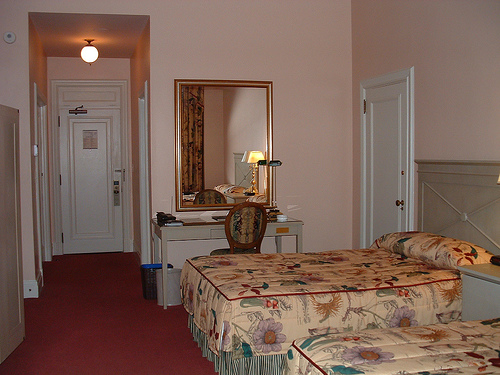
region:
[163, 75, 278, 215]
Glass mirror with a frame.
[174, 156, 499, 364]
Bed with a pillow.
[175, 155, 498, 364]
Bed with a blanket.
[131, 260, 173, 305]
Black garbage can on the floor.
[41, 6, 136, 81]
Light hanging from the ceiling.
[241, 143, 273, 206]
Lamp that is turned on.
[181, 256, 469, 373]
Purple flower on a blanket.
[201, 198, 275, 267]
Wooden chair in front of a desk.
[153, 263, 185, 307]
White trashcan on the floor.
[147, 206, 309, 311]
White desk under the mirror.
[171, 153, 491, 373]
Two beds in room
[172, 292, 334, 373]
Stripped bed skirt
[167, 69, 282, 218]
Wall mirror above desk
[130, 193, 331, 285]
Desk and chair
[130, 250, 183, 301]
Waste baskets under desk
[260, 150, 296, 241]
Desk Lamp sitting on cream colored desk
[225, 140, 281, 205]
Bedside lamp reflected in mirror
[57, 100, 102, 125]
Mechanical door closer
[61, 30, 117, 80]
globe ceiling light fixture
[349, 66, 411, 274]
White door beside bed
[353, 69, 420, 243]
white doors with gold hinges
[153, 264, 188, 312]
tan wastebasket on floor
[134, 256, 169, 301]
blue wastebasket on floor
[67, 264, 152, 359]
portion of red carpet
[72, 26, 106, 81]
bright circular light in ceiling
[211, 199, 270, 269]
brown chair beside the bed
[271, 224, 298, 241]
red marking on gray table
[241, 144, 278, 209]
gold lamp situated on gray table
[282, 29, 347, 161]
portion of light pink wall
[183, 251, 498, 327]
multi coloured bed spread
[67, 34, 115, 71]
A light fixture mounted to the ceiling.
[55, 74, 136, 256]
An exit door to the apartment.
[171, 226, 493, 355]
A queen size bed.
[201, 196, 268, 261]
A chair used for cosmetics.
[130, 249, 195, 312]
Two trash cans positioned next to each other.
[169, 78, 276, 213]
A very large mirror for makeup.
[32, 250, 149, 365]
A room with short red carpet.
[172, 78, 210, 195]
Drapes seen through the reflection in the mirror.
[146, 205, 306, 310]
A table for personal items.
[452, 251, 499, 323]
A nightstand for placing personal items.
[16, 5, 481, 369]
A hotel room.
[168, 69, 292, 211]
A mirror on the wall.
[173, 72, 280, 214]
Reflection of the room in a mirror.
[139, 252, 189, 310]
A small white trash can.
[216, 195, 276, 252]
A small chair.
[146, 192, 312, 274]
A white "writing" table.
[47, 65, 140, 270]
An entrance doorway.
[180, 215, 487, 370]
Two beds in hotel room.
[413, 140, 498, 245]
A headboard on the wall.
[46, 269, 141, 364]
Red carpet on floor.